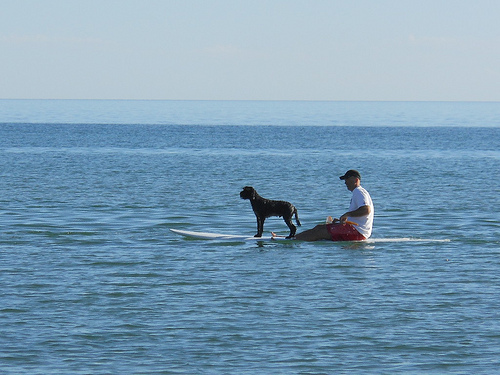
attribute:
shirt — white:
[338, 186, 374, 239]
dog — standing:
[239, 183, 302, 237]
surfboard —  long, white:
[167, 225, 453, 246]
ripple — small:
[51, 229, 103, 237]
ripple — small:
[105, 269, 163, 280]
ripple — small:
[367, 299, 450, 308]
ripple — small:
[201, 330, 244, 338]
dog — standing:
[224, 170, 314, 259]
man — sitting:
[304, 163, 406, 275]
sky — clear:
[1, 3, 499, 123]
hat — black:
[341, 168, 366, 188]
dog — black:
[236, 179, 298, 233]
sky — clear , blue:
[1, 8, 498, 95]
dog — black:
[237, 183, 304, 241]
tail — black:
[292, 217, 304, 227]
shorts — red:
[332, 224, 351, 245]